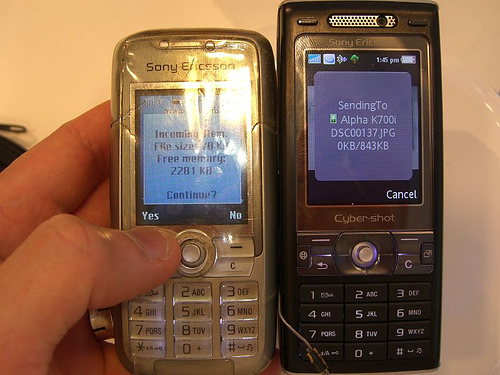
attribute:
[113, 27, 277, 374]
phone — silver, sony, cell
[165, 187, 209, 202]
continue — word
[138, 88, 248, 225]
screen — bright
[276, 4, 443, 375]
phone — black, sony, cell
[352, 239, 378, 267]
button — round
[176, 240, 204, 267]
button — round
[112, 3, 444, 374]
phones — small, white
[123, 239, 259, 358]
buttons — small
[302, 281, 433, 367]
keypad — black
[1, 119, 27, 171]
pouch — black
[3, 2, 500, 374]
photo — owned, will soon appear in a magazine, vivid